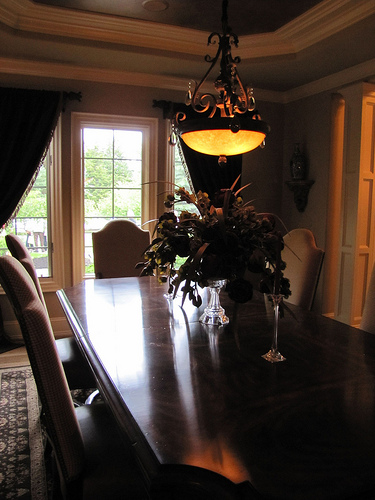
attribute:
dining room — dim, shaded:
[2, 1, 372, 492]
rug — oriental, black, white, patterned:
[0, 362, 48, 497]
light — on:
[169, 114, 272, 163]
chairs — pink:
[0, 254, 139, 498]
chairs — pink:
[0, 233, 102, 456]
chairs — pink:
[90, 217, 150, 281]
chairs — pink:
[263, 225, 325, 310]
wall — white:
[279, 94, 331, 230]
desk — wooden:
[63, 272, 374, 497]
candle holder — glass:
[261, 293, 284, 363]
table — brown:
[49, 257, 372, 374]